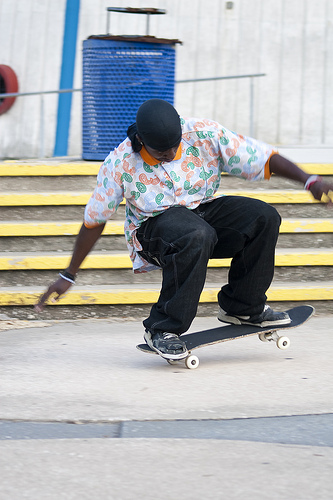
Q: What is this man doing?
A: Riding a skateboard.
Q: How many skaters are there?
A: 1.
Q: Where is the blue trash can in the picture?
A: Behind the skater.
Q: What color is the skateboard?
A: Black.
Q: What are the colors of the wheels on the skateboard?
A: White.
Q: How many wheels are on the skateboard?
A: 4.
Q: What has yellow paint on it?
A: The stairs.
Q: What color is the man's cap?
A: It is black.